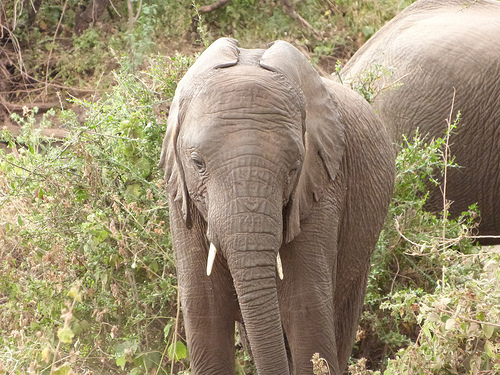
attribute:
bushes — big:
[18, 74, 163, 358]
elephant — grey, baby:
[141, 37, 408, 373]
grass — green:
[5, 7, 187, 370]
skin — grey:
[255, 93, 384, 233]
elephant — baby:
[181, 154, 206, 179]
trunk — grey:
[221, 239, 295, 373]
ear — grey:
[158, 31, 243, 227]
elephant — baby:
[156, 36, 396, 373]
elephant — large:
[330, 2, 499, 246]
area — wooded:
[13, 3, 467, 356]